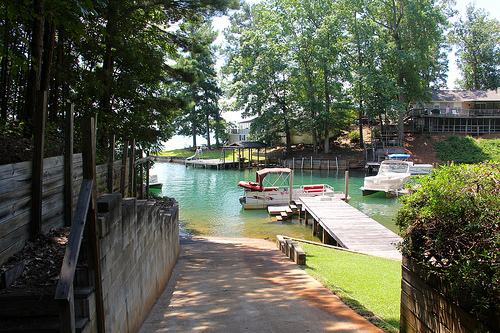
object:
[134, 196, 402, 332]
ground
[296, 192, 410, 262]
dock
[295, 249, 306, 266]
stones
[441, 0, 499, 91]
tree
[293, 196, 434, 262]
dock area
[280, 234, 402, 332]
lawn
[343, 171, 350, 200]
pole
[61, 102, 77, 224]
pole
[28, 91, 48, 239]
pole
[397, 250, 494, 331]
hedge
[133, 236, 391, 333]
dirt path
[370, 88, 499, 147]
building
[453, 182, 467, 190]
leaves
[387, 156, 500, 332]
bush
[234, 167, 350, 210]
boat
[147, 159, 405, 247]
water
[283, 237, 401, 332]
grass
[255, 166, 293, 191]
canopy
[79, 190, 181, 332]
stone wall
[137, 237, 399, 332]
shadows